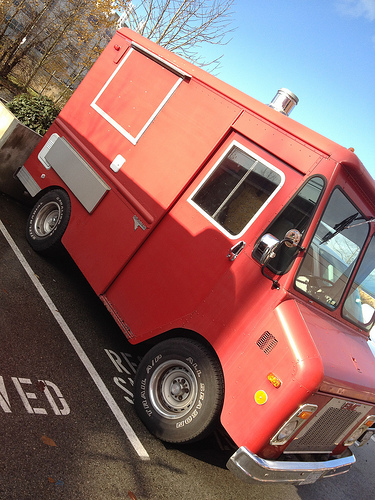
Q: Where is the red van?
A: On the road.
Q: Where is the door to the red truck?
A: On the passenger side up front.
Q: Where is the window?
A: On the side of the truck.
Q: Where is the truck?
A: Parked in a parking spot.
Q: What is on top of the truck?
A: An exhaust chimney.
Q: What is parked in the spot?
A: The red.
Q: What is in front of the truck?
A: The bumper.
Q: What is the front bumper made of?
A: Chrome.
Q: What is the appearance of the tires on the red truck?
A: Black with white writing.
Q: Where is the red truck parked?
A: Paved parking lot.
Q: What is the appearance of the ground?
A: White line and writing on cement.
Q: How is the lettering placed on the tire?
A: In a circle.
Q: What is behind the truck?
A: Trees and a building.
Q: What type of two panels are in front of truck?
A: Glass.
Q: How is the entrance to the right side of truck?
A: A door with glass panels and handle.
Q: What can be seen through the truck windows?
A: Another vehicle.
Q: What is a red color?
A: A truck.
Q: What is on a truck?
A: Front grill.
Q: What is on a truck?
A: Side door.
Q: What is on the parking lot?
A: Writing.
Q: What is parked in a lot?
A: Truck.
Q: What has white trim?
A: A van.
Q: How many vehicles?
A: One.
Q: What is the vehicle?
A: A truck.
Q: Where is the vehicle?
A: Parked.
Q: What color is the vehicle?
A: Red.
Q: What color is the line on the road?
A: White.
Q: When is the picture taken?
A: Daytime.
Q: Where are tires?
A: On the truck.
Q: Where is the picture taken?
A: In a parking lot.